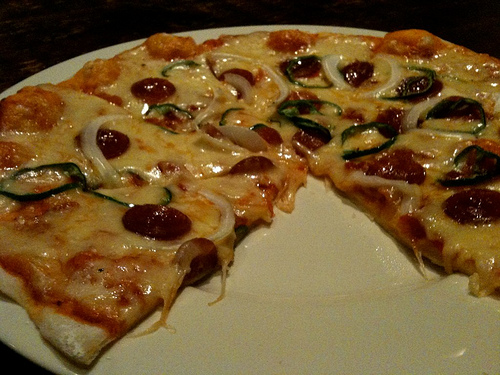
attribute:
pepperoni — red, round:
[73, 124, 129, 160]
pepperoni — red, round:
[130, 72, 177, 107]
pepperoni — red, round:
[365, 152, 427, 189]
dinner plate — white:
[0, 23, 491, 370]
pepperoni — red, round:
[120, 201, 192, 242]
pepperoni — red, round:
[226, 154, 275, 176]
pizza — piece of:
[0, 26, 500, 373]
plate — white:
[9, 16, 489, 367]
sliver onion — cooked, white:
[321, 50, 401, 102]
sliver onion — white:
[188, 181, 237, 242]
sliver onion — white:
[73, 107, 133, 187]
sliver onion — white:
[182, 53, 219, 140]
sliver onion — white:
[205, 46, 291, 108]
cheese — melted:
[1, 36, 498, 336]